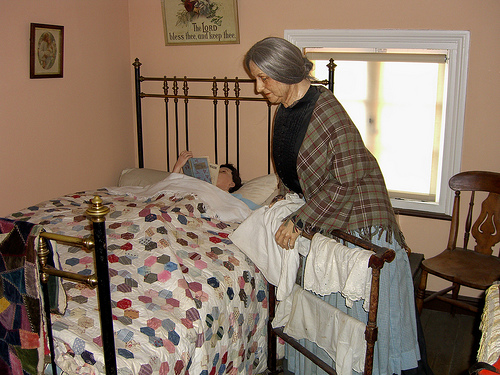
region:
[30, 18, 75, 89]
picture hanging on wall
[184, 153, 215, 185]
book in person's hand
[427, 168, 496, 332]
wooden chair in room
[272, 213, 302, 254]
left hand on old woman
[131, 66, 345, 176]
head board of the bed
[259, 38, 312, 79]
old woman's grey hair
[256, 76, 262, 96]
the old woman's nose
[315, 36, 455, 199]
window in the room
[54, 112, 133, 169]
pink painted walls in room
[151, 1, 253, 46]
picture hanging over the bed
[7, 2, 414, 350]
a display of a woman standing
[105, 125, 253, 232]
a child is in the bed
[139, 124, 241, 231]
the child is reading a book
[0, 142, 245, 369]
the blanket is a quilt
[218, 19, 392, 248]
the woman is wearing a shall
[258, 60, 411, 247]
the shall is plaid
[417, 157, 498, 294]
the chair is empty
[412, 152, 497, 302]
the chair is brown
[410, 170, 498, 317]
the chair is made of wood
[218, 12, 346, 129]
the woman has grey hair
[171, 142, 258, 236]
the mannequin is reading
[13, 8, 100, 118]
a picture on the wall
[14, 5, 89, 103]
a picture on the wall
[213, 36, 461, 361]
a woman doing linen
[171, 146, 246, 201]
a boy reading a book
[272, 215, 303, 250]
the hand of a woman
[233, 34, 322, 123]
the head of a woman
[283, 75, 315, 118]
the neck of a woman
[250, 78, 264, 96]
the nose of a woman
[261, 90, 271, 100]
the mouth of a woman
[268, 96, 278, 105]
the chin of a woman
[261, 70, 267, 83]
the eye of a woman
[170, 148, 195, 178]
the hand of a boy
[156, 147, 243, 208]
a child reading in bed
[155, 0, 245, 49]
a religious phrase hanging over a bed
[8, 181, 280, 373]
an old quilt on a bed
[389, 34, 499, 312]
a wood chair next to the window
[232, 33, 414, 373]
a woman with gray hair in a bun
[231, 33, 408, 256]
a woman in a plaid shawl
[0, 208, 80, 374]
a quilt hanging on a bed footboard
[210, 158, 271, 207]
boy's head resting on a pillow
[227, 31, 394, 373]
woman arranging linens on a quilt rack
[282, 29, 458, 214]
window with a roller blind pulled shut